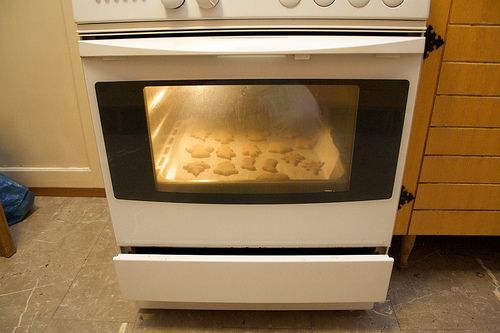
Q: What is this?
A: Cooker.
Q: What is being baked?
A: Cookies.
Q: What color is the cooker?
A: White.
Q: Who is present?
A: No one.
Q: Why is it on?
A: To bake.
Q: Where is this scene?
A: In a kitchen.